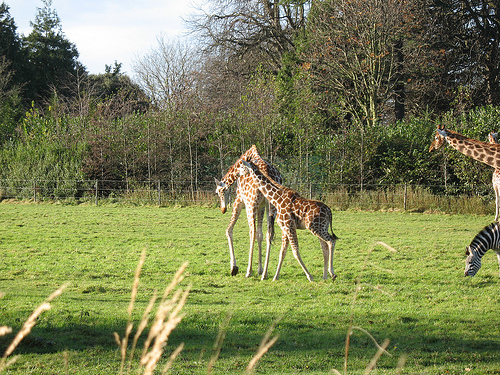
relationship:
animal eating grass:
[461, 220, 499, 277] [0, 189, 497, 372]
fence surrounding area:
[10, 166, 217, 208] [0, 187, 497, 373]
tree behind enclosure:
[116, 112, 132, 194] [0, 166, 500, 373]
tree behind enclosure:
[141, 112, 156, 195] [0, 166, 500, 373]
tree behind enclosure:
[315, 12, 437, 202] [0, 166, 500, 373]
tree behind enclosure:
[20, 2, 78, 109] [0, 166, 500, 373]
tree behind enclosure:
[183, 42, 198, 199] [0, 166, 500, 373]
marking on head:
[214, 187, 219, 191] [214, 175, 234, 212]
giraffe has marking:
[184, 142, 367, 289] [214, 187, 219, 191]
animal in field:
[212, 141, 284, 277] [6, 200, 484, 367]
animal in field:
[236, 154, 341, 284] [6, 200, 484, 367]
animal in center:
[236, 158, 338, 281] [174, 1, 371, 362]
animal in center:
[209, 140, 286, 274] [174, 1, 371, 362]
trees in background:
[0, 0, 499, 199] [0, 5, 496, 208]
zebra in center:
[445, 201, 497, 300] [393, 6, 483, 368]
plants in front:
[7, 232, 482, 366] [100, 168, 372, 238]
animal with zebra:
[212, 141, 284, 277] [459, 222, 498, 272]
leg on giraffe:
[282, 232, 327, 299] [181, 142, 335, 287]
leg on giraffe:
[276, 220, 318, 280] [233, 136, 338, 288]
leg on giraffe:
[218, 216, 245, 280] [211, 138, 283, 283]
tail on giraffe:
[326, 210, 339, 245] [233, 157, 345, 288]